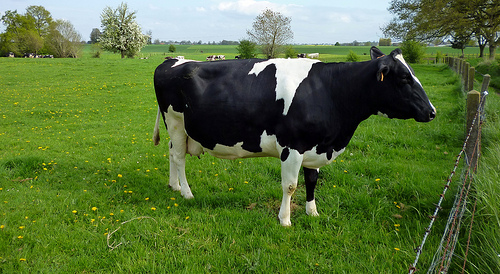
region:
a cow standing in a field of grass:
[144, 45, 439, 225]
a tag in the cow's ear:
[378, 69, 383, 83]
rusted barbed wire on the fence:
[410, 104, 485, 272]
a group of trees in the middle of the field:
[0, 3, 79, 61]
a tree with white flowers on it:
[92, 1, 146, 60]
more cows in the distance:
[205, 48, 322, 62]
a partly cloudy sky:
[0, 0, 384, 41]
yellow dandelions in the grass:
[72, 200, 122, 223]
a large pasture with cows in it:
[0, 40, 498, 271]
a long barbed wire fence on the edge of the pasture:
[404, 51, 489, 272]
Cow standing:
[148, 47, 440, 229]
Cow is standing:
[139, 50, 442, 229]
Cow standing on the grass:
[142, 49, 444, 224]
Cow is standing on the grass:
[147, 39, 439, 225]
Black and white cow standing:
[149, 48, 433, 228]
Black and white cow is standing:
[147, 45, 439, 226]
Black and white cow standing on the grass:
[145, 50, 435, 228]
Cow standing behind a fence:
[141, 48, 485, 272]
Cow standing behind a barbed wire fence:
[144, 42, 488, 272]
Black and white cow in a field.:
[126, 20, 446, 236]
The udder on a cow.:
[182, 125, 212, 165]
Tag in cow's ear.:
[371, 51, 393, 89]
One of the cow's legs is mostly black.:
[153, 137, 333, 223]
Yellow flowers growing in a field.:
[11, 80, 411, 269]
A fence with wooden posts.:
[433, 44, 488, 271]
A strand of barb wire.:
[414, 50, 489, 268]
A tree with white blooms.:
[96, 4, 141, 64]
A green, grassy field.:
[8, 44, 488, 263]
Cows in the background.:
[163, 34, 361, 61]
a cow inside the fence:
[119, 31, 452, 233]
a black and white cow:
[93, 12, 448, 261]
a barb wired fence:
[376, 154, 481, 271]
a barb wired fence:
[412, 143, 467, 272]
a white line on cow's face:
[377, 50, 448, 129]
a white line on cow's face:
[358, 23, 464, 150]